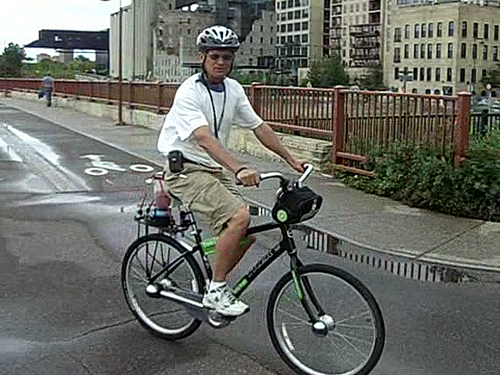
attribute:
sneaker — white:
[198, 275, 250, 320]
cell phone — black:
[168, 149, 185, 174]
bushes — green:
[375, 143, 497, 212]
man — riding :
[155, 24, 311, 323]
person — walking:
[35, 70, 62, 109]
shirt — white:
[148, 66, 268, 173]